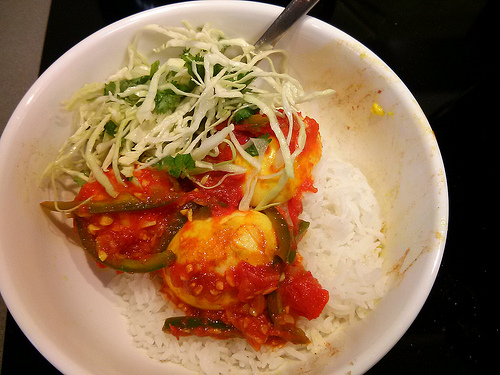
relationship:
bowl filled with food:
[0, 2, 452, 374] [38, 25, 386, 374]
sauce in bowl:
[80, 112, 326, 346] [0, 2, 452, 374]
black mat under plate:
[436, 10, 498, 366] [6, 41, 459, 373]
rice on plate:
[301, 152, 391, 297] [306, 37, 494, 365]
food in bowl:
[38, 25, 337, 354] [268, 33, 427, 148]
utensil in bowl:
[155, 0, 326, 155] [0, 2, 452, 374]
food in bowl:
[38, 25, 386, 374] [0, 2, 452, 374]